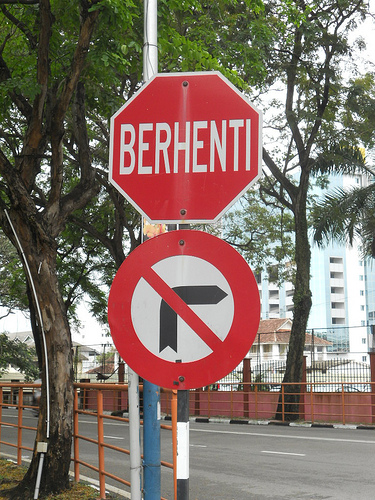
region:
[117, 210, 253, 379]
Traffic sign on a pole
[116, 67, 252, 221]
Traffic sign on a pole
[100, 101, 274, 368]
Traffic sign on a pole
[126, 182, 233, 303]
Traffic sign on a pole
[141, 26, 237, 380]
Traffic sign on a pole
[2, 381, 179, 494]
orange metal fence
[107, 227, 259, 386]
round sign with black arrow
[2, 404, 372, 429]
black and white curb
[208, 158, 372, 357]
tall light blue building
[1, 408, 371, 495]
paved road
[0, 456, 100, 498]
small section of green grass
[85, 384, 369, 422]
solid red wall on the side of the road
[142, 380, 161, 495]
section of blue metal pole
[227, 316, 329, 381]
white house with red shingled roof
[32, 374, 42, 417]
person walking on the street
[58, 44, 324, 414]
sign on street corner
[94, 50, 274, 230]
sign is octagon shaped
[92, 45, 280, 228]
sign is red and white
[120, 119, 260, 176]
word BEHRENTI written on sign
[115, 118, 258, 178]
letters on sign are white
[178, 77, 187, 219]
black screws on sign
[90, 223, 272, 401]
sign is circle shaped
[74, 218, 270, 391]
sign is red, black and white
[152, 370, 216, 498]
pole is white and black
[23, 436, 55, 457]
electrical box on tree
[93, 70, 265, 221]
red and white street sign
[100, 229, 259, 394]
black red and white street sign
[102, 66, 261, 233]
white and red street sign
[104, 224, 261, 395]
black white and red street sign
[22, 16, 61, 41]
green leaves in brown tree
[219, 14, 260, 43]
green leaves in brown tree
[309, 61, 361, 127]
green leaves in brown tree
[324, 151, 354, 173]
green leaves in brown tree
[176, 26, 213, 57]
green leaves in brown tree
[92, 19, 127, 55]
green leaves in brown tree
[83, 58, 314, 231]
Sign is red and white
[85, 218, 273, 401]
A circular sign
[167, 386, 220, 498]
pole is white and black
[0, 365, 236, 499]
Gate is orange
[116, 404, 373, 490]
A street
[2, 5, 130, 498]
Trunk is curved here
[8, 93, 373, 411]
There are clouds in the sky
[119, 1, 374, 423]
Apartments in the background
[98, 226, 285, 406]
Sign is showing something is not allowed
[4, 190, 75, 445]
Wire on the tree